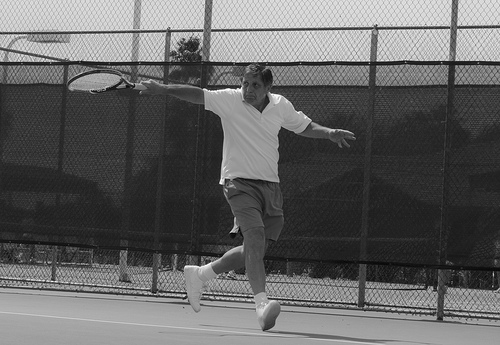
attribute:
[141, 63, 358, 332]
man — playing tennis, playing, runing, running, concentrating, middle-aged, serious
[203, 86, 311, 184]
shirt — white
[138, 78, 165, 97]
hand — man's, raised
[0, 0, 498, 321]
fence — chain link, wire, tall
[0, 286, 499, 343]
tennis court — outdoor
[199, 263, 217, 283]
sock — white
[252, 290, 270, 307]
sock — white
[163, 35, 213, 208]
tree — scrubby, small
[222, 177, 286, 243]
shorts — dark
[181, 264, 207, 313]
shoe — white, bright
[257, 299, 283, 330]
shoe — white, bright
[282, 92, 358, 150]
left arm — out to side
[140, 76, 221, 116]
right arm — extended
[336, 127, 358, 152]
fingers — spread apart